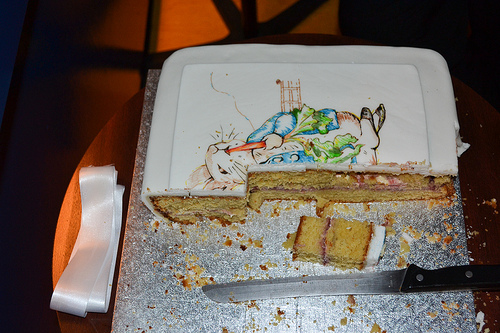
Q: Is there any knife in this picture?
A: Yes, there is a knife.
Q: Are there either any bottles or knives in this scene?
A: Yes, there is a knife.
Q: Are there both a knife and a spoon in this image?
A: No, there is a knife but no spoons.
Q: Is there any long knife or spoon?
A: Yes, there is a long knife.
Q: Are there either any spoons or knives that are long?
A: Yes, the knife is long.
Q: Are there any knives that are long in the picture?
A: Yes, there is a long knife.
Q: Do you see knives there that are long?
A: Yes, there is a knife that is long.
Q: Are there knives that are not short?
A: Yes, there is a long knife.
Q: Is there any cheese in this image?
A: No, there is no cheese.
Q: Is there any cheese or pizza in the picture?
A: No, there are no cheese or pizzas.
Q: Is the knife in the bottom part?
A: Yes, the knife is in the bottom of the image.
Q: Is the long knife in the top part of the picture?
A: No, the knife is in the bottom of the image.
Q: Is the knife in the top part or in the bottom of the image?
A: The knife is in the bottom of the image.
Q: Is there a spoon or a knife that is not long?
A: No, there is a knife but it is long.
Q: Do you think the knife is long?
A: Yes, the knife is long.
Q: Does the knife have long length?
A: Yes, the knife is long.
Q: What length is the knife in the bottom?
A: The knife is long.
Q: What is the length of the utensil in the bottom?
A: The knife is long.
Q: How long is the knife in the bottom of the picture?
A: The knife is long.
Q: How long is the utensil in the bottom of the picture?
A: The knife is long.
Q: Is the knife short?
A: No, the knife is long.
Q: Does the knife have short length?
A: No, the knife is long.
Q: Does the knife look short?
A: No, the knife is long.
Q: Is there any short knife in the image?
A: No, there is a knife but it is long.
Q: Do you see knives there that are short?
A: No, there is a knife but it is long.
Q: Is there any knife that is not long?
A: No, there is a knife but it is long.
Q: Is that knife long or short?
A: The knife is long.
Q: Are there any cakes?
A: Yes, there is a cake.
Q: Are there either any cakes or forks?
A: Yes, there is a cake.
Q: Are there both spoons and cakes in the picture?
A: No, there is a cake but no spoons.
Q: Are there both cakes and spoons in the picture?
A: No, there is a cake but no spoons.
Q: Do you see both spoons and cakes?
A: No, there is a cake but no spoons.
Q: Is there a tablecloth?
A: No, there are no tablecloths.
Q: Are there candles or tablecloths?
A: No, there are no tablecloths or candles.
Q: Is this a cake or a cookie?
A: This is a cake.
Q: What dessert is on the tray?
A: The dessert is a cake.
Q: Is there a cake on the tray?
A: Yes, there is a cake on the tray.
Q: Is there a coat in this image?
A: Yes, there is a coat.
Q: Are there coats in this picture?
A: Yes, there is a coat.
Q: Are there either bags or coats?
A: Yes, there is a coat.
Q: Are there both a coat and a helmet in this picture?
A: No, there is a coat but no helmets.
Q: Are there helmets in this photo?
A: No, there are no helmets.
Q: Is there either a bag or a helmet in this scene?
A: No, there are no helmets or bags.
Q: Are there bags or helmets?
A: No, there are no helmets or bags.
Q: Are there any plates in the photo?
A: No, there are no plates.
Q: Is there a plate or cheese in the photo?
A: No, there are no plates or cheese.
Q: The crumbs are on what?
A: The crumbs are on the tray.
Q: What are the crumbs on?
A: The crumbs are on the tray.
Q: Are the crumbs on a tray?
A: Yes, the crumbs are on a tray.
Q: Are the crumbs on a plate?
A: No, the crumbs are on a tray.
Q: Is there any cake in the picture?
A: Yes, there is a cake.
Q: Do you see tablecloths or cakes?
A: Yes, there is a cake.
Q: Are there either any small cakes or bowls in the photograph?
A: Yes, there is a small cake.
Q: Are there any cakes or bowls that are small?
A: Yes, the cake is small.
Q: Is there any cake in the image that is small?
A: Yes, there is a small cake.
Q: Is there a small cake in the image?
A: Yes, there is a small cake.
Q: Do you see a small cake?
A: Yes, there is a small cake.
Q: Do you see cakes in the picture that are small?
A: Yes, there is a cake that is small.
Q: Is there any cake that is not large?
A: Yes, there is a small cake.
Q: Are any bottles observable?
A: No, there are no bottles.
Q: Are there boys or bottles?
A: No, there are no bottles or boys.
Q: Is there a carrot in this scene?
A: Yes, there is a carrot.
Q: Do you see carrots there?
A: Yes, there is a carrot.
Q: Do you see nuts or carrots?
A: Yes, there is a carrot.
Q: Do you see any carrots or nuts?
A: Yes, there is a carrot.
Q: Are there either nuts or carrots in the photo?
A: Yes, there is a carrot.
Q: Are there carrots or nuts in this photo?
A: Yes, there is a carrot.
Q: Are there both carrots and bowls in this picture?
A: No, there is a carrot but no bowls.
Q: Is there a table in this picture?
A: Yes, there is a table.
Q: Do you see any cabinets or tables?
A: Yes, there is a table.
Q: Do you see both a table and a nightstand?
A: No, there is a table but no nightstands.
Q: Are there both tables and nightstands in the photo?
A: No, there is a table but no nightstands.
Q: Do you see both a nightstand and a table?
A: No, there is a table but no nightstands.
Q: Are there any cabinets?
A: No, there are no cabinets.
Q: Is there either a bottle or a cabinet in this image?
A: No, there are no cabinets or bottles.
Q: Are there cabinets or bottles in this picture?
A: No, there are no cabinets or bottles.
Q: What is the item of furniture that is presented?
A: The piece of furniture is a table.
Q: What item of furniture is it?
A: The piece of furniture is a table.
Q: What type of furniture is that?
A: This is a table.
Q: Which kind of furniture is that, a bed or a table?
A: This is a table.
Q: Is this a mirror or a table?
A: This is a table.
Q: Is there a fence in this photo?
A: Yes, there is a fence.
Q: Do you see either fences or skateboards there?
A: Yes, there is a fence.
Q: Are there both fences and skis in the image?
A: No, there is a fence but no skis.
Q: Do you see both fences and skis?
A: No, there is a fence but no skis.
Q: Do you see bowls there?
A: No, there are no bowls.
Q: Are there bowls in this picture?
A: No, there are no bowls.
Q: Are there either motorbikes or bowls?
A: No, there are no bowls or motorbikes.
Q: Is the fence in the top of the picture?
A: Yes, the fence is in the top of the image.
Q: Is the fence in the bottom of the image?
A: No, the fence is in the top of the image.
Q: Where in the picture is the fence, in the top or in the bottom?
A: The fence is in the top of the image.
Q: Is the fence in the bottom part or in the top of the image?
A: The fence is in the top of the image.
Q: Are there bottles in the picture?
A: No, there are no bottles.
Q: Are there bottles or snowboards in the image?
A: No, there are no bottles or snowboards.